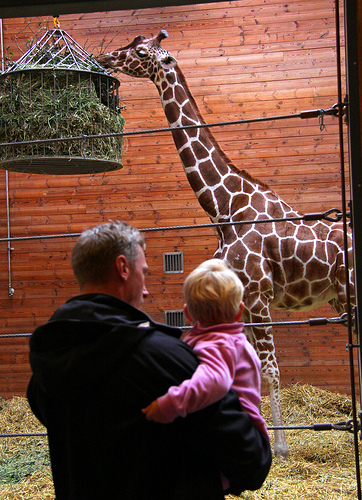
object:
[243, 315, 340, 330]
wire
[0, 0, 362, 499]
pin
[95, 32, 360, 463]
giraffe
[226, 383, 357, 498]
hay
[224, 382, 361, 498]
ground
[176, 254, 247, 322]
hair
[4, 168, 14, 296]
pipe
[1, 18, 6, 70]
pipe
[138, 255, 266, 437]
baby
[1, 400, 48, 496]
stack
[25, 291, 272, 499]
jacket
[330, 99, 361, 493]
rod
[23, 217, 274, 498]
man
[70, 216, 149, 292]
hair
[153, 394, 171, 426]
sleeve edge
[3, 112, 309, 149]
chain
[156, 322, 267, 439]
sweater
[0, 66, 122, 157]
grass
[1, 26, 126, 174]
basket